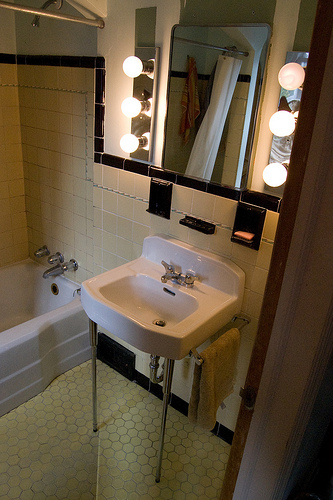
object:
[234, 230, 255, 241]
soap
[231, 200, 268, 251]
holder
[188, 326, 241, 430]
towel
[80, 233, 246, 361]
sink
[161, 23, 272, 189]
mirror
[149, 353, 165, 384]
pipes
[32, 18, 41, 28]
head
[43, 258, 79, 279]
faucet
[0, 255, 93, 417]
bathtub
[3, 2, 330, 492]
bathroom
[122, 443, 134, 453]
tiles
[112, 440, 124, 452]
tile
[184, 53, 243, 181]
curtain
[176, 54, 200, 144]
towel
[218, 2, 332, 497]
door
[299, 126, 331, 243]
wood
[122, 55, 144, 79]
lights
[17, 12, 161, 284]
wall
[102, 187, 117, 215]
tiles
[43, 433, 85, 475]
floor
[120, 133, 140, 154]
knob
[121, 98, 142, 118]
light